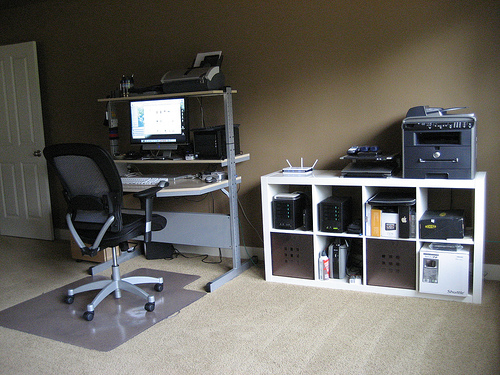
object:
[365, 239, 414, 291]
box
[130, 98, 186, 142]
monitor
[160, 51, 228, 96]
printer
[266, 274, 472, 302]
shelf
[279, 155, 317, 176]
router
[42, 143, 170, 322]
chair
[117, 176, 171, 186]
keyboard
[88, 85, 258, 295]
desk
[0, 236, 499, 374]
carpet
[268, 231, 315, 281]
storage box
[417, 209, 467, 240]
paper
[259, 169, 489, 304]
desk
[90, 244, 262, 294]
bottom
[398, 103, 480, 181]
printer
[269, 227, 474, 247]
shelf